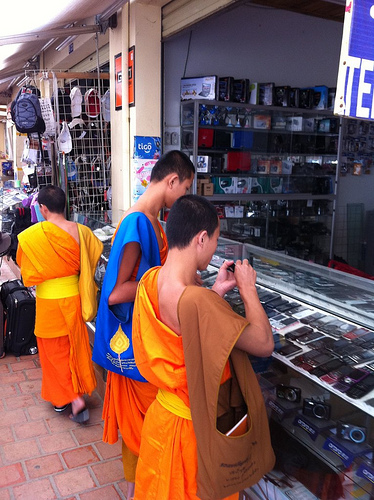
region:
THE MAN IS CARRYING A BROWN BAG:
[172, 278, 283, 497]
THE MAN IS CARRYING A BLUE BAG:
[80, 203, 163, 398]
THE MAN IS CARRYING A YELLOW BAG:
[74, 212, 110, 334]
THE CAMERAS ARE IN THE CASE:
[269, 379, 370, 459]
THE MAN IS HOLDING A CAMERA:
[223, 249, 248, 276]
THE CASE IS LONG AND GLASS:
[78, 204, 371, 489]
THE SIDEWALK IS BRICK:
[0, 348, 200, 497]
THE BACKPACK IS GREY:
[8, 77, 39, 133]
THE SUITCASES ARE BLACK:
[0, 270, 33, 358]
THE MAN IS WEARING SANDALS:
[45, 393, 98, 432]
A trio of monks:
[17, 147, 273, 495]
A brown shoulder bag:
[178, 284, 277, 498]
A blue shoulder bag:
[91, 214, 159, 378]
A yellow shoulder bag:
[79, 219, 99, 319]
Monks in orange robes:
[15, 151, 275, 498]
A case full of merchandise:
[190, 238, 372, 496]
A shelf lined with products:
[177, 74, 334, 264]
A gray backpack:
[12, 94, 47, 134]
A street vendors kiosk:
[139, 0, 368, 498]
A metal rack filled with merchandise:
[55, 67, 110, 226]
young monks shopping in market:
[6, 122, 367, 493]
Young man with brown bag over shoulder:
[124, 193, 274, 499]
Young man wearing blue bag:
[90, 148, 197, 494]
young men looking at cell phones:
[93, 147, 366, 498]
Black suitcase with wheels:
[0, 277, 39, 358]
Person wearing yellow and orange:
[15, 177, 103, 424]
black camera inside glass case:
[298, 395, 331, 424]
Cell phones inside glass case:
[193, 249, 373, 406]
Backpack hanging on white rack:
[9, 78, 45, 147]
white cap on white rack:
[68, 83, 83, 118]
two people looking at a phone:
[56, 127, 283, 498]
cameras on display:
[260, 391, 371, 464]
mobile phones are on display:
[281, 263, 370, 406]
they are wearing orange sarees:
[23, 229, 124, 409]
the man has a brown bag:
[133, 274, 298, 498]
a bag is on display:
[9, 64, 62, 148]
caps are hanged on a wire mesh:
[33, 80, 123, 165]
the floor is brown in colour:
[25, 399, 72, 497]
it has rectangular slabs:
[17, 431, 77, 484]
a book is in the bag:
[178, 405, 261, 447]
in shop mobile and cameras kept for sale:
[238, 257, 363, 427]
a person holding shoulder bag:
[166, 282, 270, 495]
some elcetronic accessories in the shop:
[194, 77, 335, 227]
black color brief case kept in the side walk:
[0, 292, 32, 362]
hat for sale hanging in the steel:
[66, 85, 100, 124]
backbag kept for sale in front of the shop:
[12, 82, 47, 137]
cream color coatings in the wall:
[104, 21, 146, 195]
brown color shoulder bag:
[185, 292, 265, 473]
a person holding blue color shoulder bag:
[105, 221, 149, 372]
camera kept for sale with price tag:
[303, 396, 352, 469]